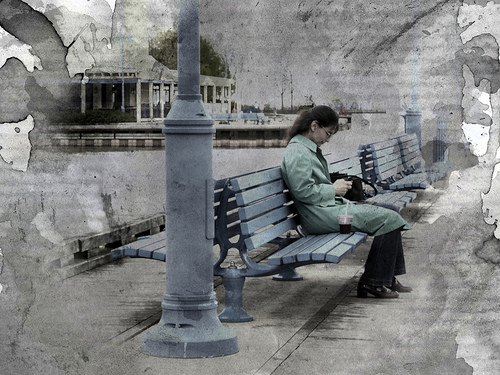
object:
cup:
[338, 214, 354, 234]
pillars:
[79, 78, 86, 113]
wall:
[1, 0, 497, 174]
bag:
[329, 171, 378, 201]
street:
[273, 135, 498, 374]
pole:
[146, 0, 241, 361]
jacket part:
[288, 149, 322, 176]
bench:
[111, 150, 417, 326]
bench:
[356, 132, 447, 195]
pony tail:
[287, 109, 311, 147]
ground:
[0, 176, 499, 374]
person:
[281, 104, 412, 300]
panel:
[205, 177, 215, 240]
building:
[77, 66, 265, 122]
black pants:
[360, 227, 406, 288]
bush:
[60, 108, 137, 124]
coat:
[279, 132, 412, 236]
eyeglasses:
[319, 123, 334, 139]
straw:
[344, 174, 356, 182]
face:
[314, 127, 336, 147]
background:
[0, 0, 499, 239]